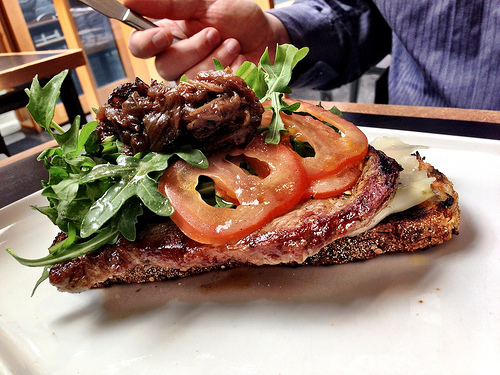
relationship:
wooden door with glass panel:
[0, 0, 153, 135] [14, 0, 125, 102]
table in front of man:
[0, 101, 497, 206] [119, 0, 500, 113]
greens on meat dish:
[23, 70, 200, 249] [3, 41, 461, 297]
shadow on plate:
[47, 203, 481, 334] [115, 269, 479, 360]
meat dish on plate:
[3, 41, 461, 297] [2, 124, 496, 374]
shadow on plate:
[47, 192, 472, 334] [2, 124, 496, 374]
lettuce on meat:
[24, 111, 223, 253] [36, 160, 461, 293]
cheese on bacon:
[356, 132, 433, 233] [50, 144, 403, 295]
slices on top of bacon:
[158, 114, 371, 231] [221, 200, 425, 250]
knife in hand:
[76, 0, 183, 46] [119, 0, 297, 94]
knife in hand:
[87, 2, 198, 48] [124, 1, 291, 88]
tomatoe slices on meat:
[153, 86, 375, 253] [91, 67, 271, 160]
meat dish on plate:
[42, 74, 459, 291] [2, 124, 496, 374]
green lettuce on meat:
[50, 133, 177, 227] [301, 184, 466, 280]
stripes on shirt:
[376, 3, 496, 115] [269, 0, 499, 107]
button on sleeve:
[302, 3, 366, 48] [264, 0, 392, 93]